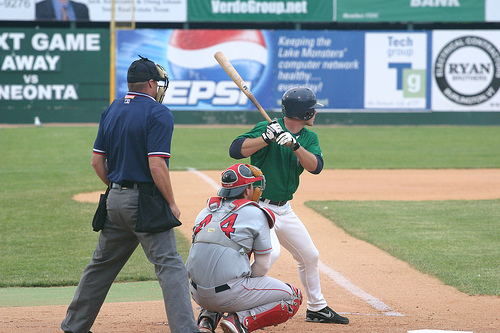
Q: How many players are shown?
A: Two.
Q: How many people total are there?
A: Three.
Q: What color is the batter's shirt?
A: Green.